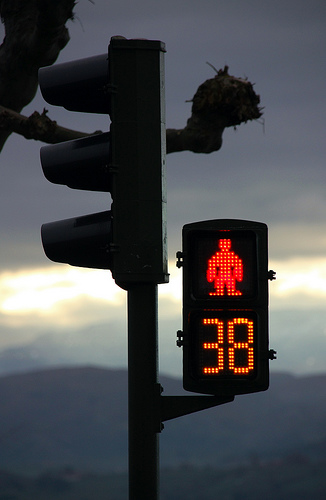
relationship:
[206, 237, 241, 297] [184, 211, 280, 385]
man on light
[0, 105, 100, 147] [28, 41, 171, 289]
stick behind light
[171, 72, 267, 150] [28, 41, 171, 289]
stick in front of light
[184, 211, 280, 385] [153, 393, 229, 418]
light has pole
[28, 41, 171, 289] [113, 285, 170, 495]
light has pole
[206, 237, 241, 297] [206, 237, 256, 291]
man looks like a man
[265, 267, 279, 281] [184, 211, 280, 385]
knob on light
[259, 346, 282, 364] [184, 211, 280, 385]
knob on light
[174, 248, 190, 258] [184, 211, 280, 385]
knob on light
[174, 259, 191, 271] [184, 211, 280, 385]
knob on light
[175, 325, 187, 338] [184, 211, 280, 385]
knob on light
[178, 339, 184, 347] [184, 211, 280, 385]
knob on light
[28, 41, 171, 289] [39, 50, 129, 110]
light has top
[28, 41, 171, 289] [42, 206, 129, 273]
light has bottom